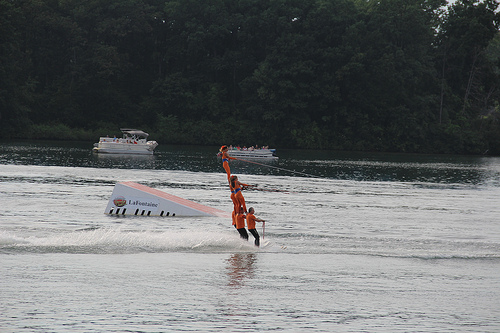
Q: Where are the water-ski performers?
A: On the water.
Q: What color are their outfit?
A: Blue, black and orange.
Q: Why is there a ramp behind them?
A: It's for performing jumps.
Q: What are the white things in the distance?
A: Boats.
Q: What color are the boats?
A: White.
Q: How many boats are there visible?
A: Two.